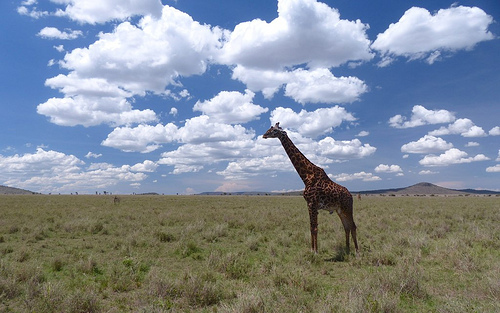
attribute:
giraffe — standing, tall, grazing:
[262, 121, 359, 258]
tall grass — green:
[1, 192, 303, 313]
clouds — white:
[64, 7, 215, 83]